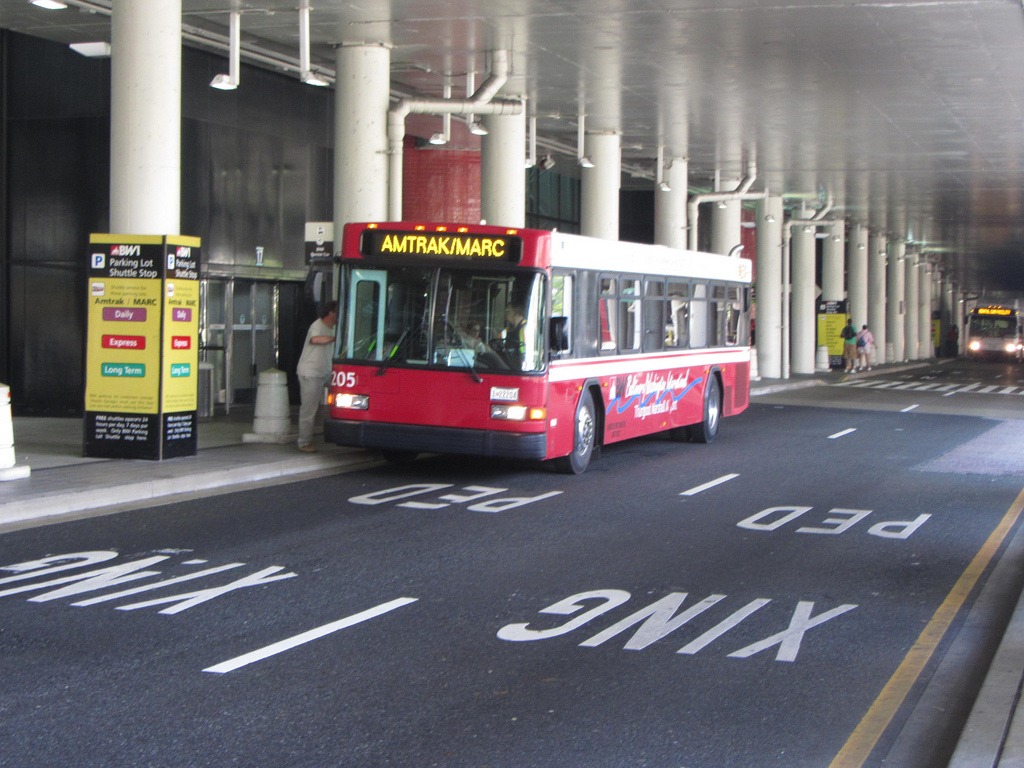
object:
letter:
[578, 592, 727, 651]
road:
[0, 348, 1023, 768]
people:
[841, 317, 858, 373]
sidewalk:
[0, 352, 957, 524]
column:
[109, 0, 183, 236]